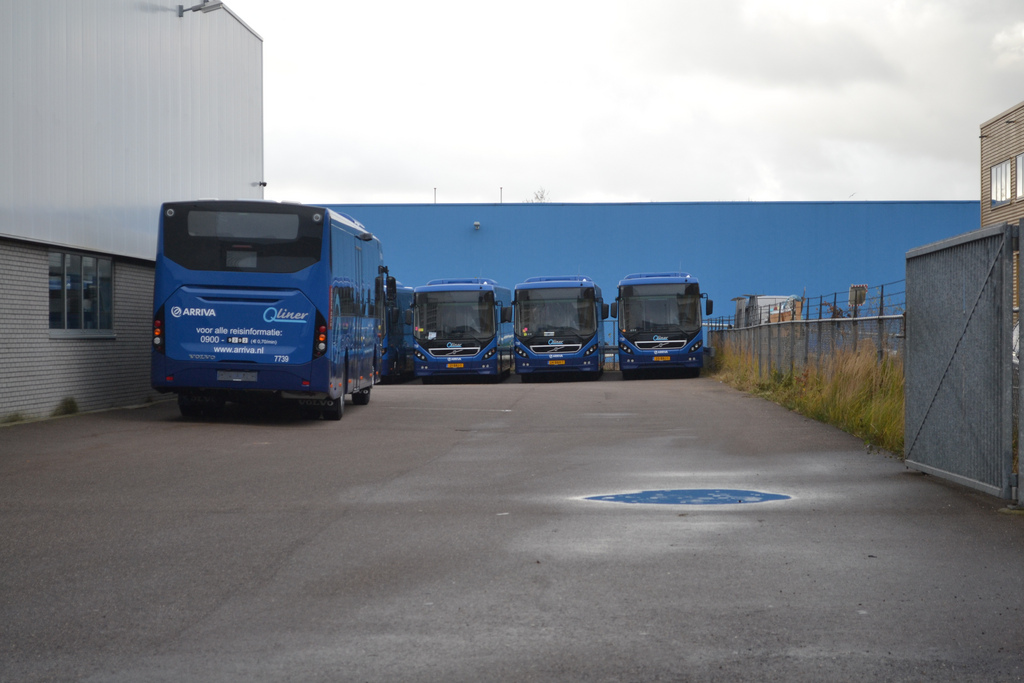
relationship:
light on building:
[199, 8, 219, 17] [11, 21, 299, 477]